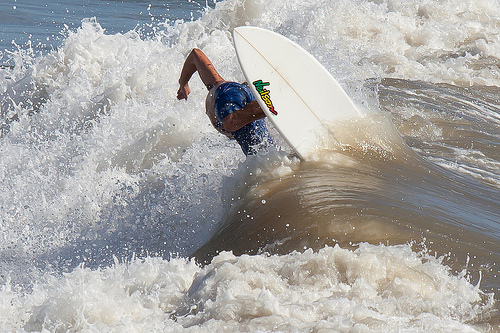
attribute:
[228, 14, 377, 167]
board — white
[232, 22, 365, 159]
board — white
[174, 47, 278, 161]
man — surfing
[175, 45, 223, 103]
arm — bent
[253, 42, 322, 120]
surfboard — white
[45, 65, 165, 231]
waves — white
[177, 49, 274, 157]
surfer — shirtless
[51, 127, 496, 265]
water — behind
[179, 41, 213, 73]
elbow — bent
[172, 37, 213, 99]
elbow — bent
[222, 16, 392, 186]
board — white